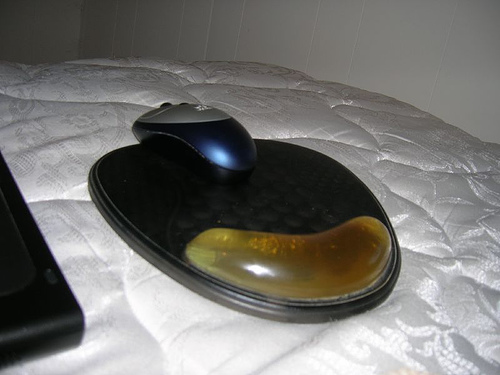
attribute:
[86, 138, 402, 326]
mousepad — black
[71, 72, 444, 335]
mouse — wireless 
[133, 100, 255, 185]
mouse — silver , blue , wireless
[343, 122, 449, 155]
mattress — white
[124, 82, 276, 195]
mouse — wireless, blue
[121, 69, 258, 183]
mouse — blue , silver 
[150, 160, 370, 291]
mousepad — black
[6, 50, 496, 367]
blanket — White 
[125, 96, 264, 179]
mouse — wireless, blue and grey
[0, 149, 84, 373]
laptop — black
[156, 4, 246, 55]
bars — vertical 